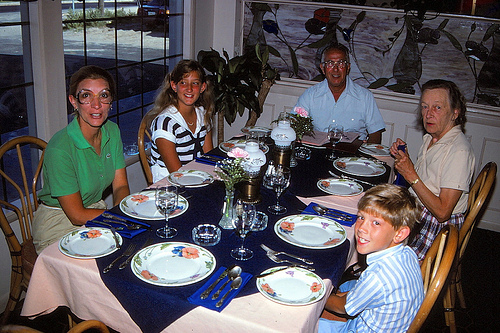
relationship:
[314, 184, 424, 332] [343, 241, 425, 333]
boy wearing shirt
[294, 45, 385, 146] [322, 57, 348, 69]
man wearing glasses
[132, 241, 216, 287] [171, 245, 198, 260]
plate has flower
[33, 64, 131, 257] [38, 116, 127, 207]
lady wearing shirt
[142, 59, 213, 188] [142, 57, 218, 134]
girl has hair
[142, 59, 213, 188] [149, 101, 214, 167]
girl wearing shirt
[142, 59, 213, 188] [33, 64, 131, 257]
girl looking at lady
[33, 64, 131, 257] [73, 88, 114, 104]
lady wearing glasses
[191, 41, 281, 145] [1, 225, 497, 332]
plant on floor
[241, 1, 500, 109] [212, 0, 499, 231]
drawing on wall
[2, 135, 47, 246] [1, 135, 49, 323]
back of chair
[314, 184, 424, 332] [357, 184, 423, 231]
boy has hair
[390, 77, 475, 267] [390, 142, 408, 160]
grandma holding napkin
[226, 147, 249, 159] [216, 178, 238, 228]
rose in vase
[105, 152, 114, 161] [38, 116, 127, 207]
logo on shirt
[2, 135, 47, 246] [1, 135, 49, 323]
back on chair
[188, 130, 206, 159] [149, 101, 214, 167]
tie on shirt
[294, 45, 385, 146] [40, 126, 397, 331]
man at table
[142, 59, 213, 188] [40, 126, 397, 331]
girl at table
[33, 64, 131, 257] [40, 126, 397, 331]
lady at table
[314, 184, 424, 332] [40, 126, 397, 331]
boy at table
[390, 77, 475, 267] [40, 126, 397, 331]
grandma at table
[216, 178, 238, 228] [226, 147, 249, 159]
vase has rose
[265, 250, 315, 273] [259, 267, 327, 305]
fork next to plate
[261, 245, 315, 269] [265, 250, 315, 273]
fork next to fork